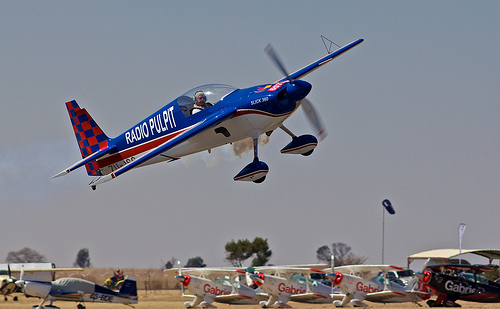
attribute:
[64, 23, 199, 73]
clouds — white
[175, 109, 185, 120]
paint — blue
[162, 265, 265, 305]
plane — white, orange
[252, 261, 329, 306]
plane — white, orange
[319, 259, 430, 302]
plane — white, orange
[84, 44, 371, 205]
plane — parked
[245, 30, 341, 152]
propeller — moving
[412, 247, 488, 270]
canopy — white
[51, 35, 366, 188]
plane — orange, blue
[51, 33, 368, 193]
planes — parked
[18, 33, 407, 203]
plane — blue, red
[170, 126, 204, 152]
paint — blue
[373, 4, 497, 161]
sky — dark blue, grey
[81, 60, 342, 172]
plane — blue, red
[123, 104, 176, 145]
radio pulpit — white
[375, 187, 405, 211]
wind sock — blue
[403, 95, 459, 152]
clouds — white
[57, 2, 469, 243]
sky — blue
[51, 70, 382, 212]
plane — small 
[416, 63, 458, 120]
sky — blue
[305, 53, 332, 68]
paint — blue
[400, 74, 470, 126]
sky — blue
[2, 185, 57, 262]
clouds — white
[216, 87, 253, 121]
paint — blue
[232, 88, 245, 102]
paint — blue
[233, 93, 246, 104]
paint — blue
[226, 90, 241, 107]
paint — blue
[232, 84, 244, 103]
paint — blue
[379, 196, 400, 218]
wind sock — dark blue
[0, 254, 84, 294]
structure — white 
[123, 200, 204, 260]
clouds — white 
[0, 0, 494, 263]
sky — blue 